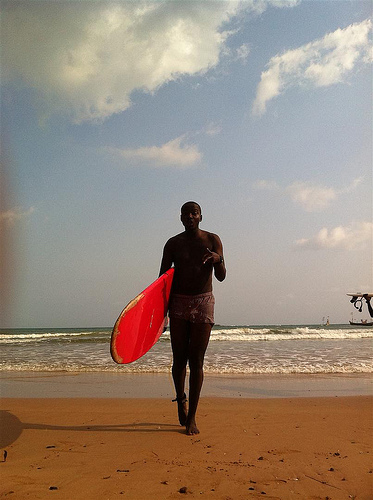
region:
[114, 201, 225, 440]
the man is holding a surfboard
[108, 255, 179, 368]
the surfboard is red in color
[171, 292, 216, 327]
the man is wearing shorts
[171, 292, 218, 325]
the shorts are light in tone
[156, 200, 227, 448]
the man has dark skin tone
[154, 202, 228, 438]
the man is of a dark complexion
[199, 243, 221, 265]
the man is making a v sign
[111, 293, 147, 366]
the surfboard looks worn on the edges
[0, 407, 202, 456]
a shadow is on the ground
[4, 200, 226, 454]
the mas is casting a shadow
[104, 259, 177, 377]
A red scuffed surf board.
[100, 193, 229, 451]
A man walking on the beach holding a surf board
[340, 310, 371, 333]
People fishing in a boat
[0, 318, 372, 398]
Waves rolling into the beach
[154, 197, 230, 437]
A man wearing brown shorts.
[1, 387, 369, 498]
a pebble, shell covered beach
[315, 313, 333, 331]
People sailing on the ocean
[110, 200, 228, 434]
a man coming in from surfing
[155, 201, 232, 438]
a man gesturing with his hand.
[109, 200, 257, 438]
A man, barefoot on the beach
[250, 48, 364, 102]
clouds in the sky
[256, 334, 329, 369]
the water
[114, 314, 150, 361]
a surfboard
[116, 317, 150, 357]
a red surfboard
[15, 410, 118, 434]
a shadow on the sand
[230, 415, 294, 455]
the sand is brown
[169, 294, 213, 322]
man is wearing shorts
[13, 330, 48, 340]
the water is white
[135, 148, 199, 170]
the cloud is white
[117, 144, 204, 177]
the cloud in the sky